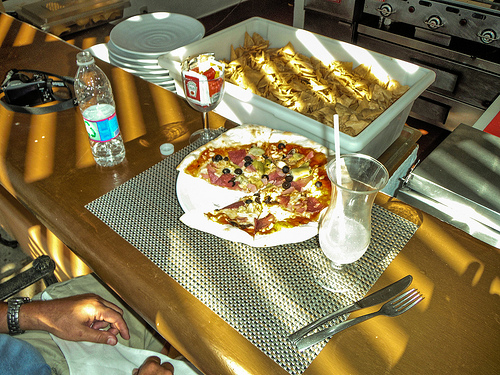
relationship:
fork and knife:
[293, 289, 423, 357] [283, 272, 415, 345]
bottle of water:
[72, 47, 128, 170] [94, 149, 128, 167]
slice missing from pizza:
[179, 189, 263, 247] [175, 126, 346, 259]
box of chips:
[164, 16, 430, 153] [272, 57, 338, 103]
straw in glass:
[331, 114, 347, 183] [318, 205, 366, 294]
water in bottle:
[94, 149, 128, 167] [72, 47, 128, 170]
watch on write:
[7, 295, 32, 337] [32, 297, 62, 335]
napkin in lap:
[52, 331, 200, 373] [13, 333, 68, 371]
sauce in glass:
[179, 62, 226, 100] [318, 205, 366, 294]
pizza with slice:
[175, 126, 346, 259] [179, 189, 263, 247]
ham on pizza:
[246, 176, 271, 194] [175, 126, 346, 259]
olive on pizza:
[281, 164, 291, 174] [175, 126, 346, 259]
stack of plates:
[103, 10, 211, 97] [108, 14, 206, 65]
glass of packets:
[318, 205, 366, 294] [182, 67, 209, 108]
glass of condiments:
[318, 205, 366, 294] [189, 55, 225, 82]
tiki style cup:
[323, 154, 378, 261] [310, 149, 389, 296]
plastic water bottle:
[72, 53, 115, 116] [72, 47, 128, 170]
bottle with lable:
[72, 47, 128, 170] [69, 101, 135, 143]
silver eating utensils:
[373, 279, 423, 323] [293, 289, 423, 357]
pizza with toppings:
[175, 126, 346, 259] [228, 152, 311, 191]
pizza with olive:
[175, 126, 346, 259] [281, 164, 291, 174]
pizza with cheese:
[175, 126, 346, 259] [265, 197, 301, 227]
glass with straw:
[318, 205, 366, 294] [331, 114, 347, 183]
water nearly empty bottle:
[94, 149, 128, 167] [72, 47, 128, 170]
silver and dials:
[373, 279, 423, 323] [374, 2, 498, 44]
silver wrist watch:
[373, 279, 423, 323] [7, 295, 32, 337]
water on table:
[94, 149, 128, 167] [0, 36, 499, 373]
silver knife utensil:
[373, 279, 423, 323] [283, 272, 415, 345]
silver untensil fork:
[373, 279, 423, 323] [293, 289, 423, 357]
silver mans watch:
[373, 279, 423, 323] [7, 295, 32, 337]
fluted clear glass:
[323, 154, 378, 261] [318, 205, 366, 294]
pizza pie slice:
[175, 126, 346, 259] [179, 189, 263, 247]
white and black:
[178, 185, 206, 210] [12, 77, 47, 102]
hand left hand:
[37, 289, 131, 348] [37, 289, 131, 348]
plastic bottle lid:
[72, 53, 115, 116] [156, 138, 177, 159]